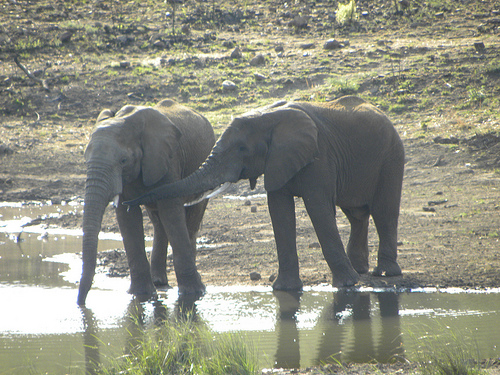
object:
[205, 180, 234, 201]
tusk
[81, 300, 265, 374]
grass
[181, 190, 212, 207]
tusk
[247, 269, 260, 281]
rock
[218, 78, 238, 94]
rock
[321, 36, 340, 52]
rock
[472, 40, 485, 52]
rock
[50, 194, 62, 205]
rock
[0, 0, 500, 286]
grass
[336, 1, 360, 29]
grass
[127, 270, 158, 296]
elephant's feet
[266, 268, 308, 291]
elephant's feet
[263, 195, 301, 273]
leg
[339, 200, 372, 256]
leg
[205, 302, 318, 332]
light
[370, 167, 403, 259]
elephant leg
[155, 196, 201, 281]
elephant leg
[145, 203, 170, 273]
elephant leg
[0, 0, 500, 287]
area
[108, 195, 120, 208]
tusk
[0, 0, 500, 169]
hill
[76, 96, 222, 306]
elephant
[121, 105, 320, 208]
head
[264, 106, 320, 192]
ear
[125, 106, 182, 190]
ear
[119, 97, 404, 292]
elephant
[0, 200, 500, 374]
water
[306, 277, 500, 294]
edge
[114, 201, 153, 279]
leg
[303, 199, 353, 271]
leg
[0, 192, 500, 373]
watering hole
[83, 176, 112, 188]
wrinkles